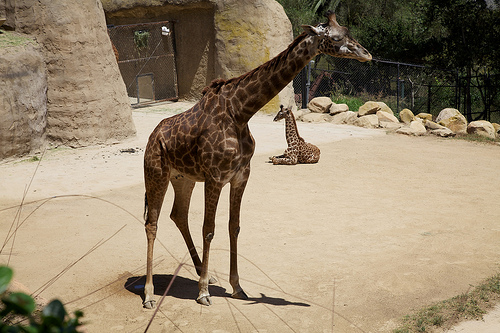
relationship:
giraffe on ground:
[268, 98, 329, 170] [273, 164, 324, 177]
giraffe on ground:
[268, 98, 329, 170] [0, 148, 498, 328]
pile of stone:
[292, 83, 472, 145] [306, 93, 331, 115]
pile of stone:
[292, 83, 472, 145] [356, 95, 383, 117]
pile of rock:
[292, 83, 472, 145] [300, 86, 500, 142]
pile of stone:
[292, 83, 472, 145] [436, 103, 467, 135]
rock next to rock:
[300, 86, 500, 142] [300, 86, 500, 142]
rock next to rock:
[300, 86, 500, 142] [406, 116, 426, 131]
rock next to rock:
[406, 116, 426, 131] [300, 86, 500, 142]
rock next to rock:
[300, 86, 500, 142] [308, 92, 331, 112]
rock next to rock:
[300, 86, 500, 142] [376, 107, 398, 124]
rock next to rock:
[300, 86, 500, 142] [436, 104, 473, 135]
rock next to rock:
[300, 86, 500, 142] [467, 113, 496, 140]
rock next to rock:
[300, 86, 500, 142] [423, 118, 453, 136]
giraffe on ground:
[92, 6, 379, 301] [37, 162, 476, 325]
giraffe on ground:
[268, 98, 329, 170] [37, 162, 476, 325]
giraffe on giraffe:
[268, 98, 329, 170] [92, 6, 379, 301]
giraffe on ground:
[268, 98, 329, 170] [1, 93, 496, 330]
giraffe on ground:
[92, 6, 379, 301] [1, 93, 496, 330]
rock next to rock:
[300, 86, 500, 142] [356, 113, 376, 130]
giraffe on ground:
[92, 6, 379, 301] [0, 148, 498, 328]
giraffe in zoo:
[268, 98, 329, 170] [2, 3, 497, 331]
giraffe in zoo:
[92, 6, 379, 301] [2, 3, 497, 331]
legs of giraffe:
[141, 177, 247, 311] [92, 6, 379, 301]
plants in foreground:
[1, 267, 88, 330] [25, 205, 106, 299]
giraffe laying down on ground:
[268, 98, 329, 170] [332, 139, 459, 249]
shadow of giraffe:
[125, 274, 308, 307] [88, 5, 395, 316]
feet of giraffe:
[143, 285, 157, 307] [92, 6, 379, 301]